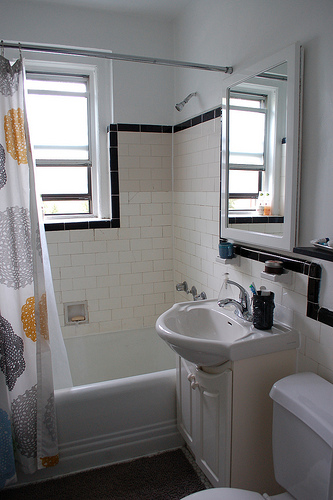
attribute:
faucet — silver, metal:
[220, 279, 251, 321]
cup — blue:
[220, 241, 236, 258]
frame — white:
[217, 45, 298, 258]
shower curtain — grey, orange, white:
[0, 19, 82, 491]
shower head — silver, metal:
[168, 86, 206, 118]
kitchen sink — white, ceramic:
[156, 288, 281, 365]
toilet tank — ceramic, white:
[267, 366, 331, 498]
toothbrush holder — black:
[243, 281, 279, 336]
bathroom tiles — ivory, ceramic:
[107, 117, 233, 201]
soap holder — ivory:
[57, 296, 100, 329]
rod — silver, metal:
[4, 39, 238, 75]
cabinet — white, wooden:
[168, 354, 273, 485]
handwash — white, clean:
[155, 296, 258, 346]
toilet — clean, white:
[175, 367, 332, 497]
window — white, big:
[25, 60, 107, 225]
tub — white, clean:
[50, 325, 183, 475]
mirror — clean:
[225, 73, 289, 225]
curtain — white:
[1, 35, 67, 489]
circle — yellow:
[2, 107, 34, 170]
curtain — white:
[2, 48, 73, 480]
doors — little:
[167, 356, 237, 491]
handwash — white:
[152, 297, 256, 344]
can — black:
[251, 287, 278, 331]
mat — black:
[70, 470, 177, 494]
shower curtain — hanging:
[5, 44, 74, 498]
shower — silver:
[171, 88, 199, 115]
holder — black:
[246, 287, 277, 333]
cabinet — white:
[170, 357, 248, 472]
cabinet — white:
[212, 35, 309, 259]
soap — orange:
[69, 312, 87, 322]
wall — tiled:
[120, 133, 216, 278]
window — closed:
[19, 57, 113, 221]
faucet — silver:
[215, 276, 247, 319]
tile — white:
[96, 273, 115, 288]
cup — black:
[248, 286, 280, 345]